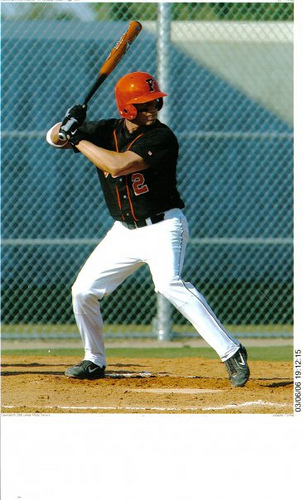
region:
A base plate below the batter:
[134, 385, 224, 396]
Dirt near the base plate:
[23, 382, 91, 401]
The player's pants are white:
[103, 243, 122, 278]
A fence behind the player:
[225, 188, 280, 271]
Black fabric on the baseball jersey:
[160, 166, 171, 202]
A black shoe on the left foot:
[228, 350, 247, 385]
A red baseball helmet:
[124, 81, 135, 96]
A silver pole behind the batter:
[157, 9, 170, 81]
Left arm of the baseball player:
[80, 140, 116, 174]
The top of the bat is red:
[107, 27, 140, 57]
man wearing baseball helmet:
[101, 74, 169, 141]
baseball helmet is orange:
[119, 80, 184, 110]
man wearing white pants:
[101, 238, 199, 291]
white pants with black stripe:
[188, 281, 211, 342]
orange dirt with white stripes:
[137, 368, 164, 387]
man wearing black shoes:
[220, 355, 255, 387]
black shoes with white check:
[228, 351, 259, 376]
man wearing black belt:
[120, 207, 177, 242]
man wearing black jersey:
[138, 133, 166, 175]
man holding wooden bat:
[51, 44, 129, 89]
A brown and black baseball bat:
[64, 12, 147, 115]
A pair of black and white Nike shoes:
[60, 338, 259, 394]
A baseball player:
[47, 68, 253, 393]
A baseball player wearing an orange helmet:
[47, 68, 185, 173]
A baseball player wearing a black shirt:
[50, 95, 201, 211]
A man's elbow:
[87, 149, 147, 185]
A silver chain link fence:
[190, 36, 288, 272]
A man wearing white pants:
[66, 203, 240, 349]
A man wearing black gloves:
[57, 98, 100, 154]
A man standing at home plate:
[37, 235, 264, 409]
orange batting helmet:
[111, 66, 176, 135]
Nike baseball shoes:
[218, 328, 257, 397]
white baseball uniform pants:
[65, 210, 249, 385]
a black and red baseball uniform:
[75, 122, 182, 227]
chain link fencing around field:
[215, 132, 292, 266]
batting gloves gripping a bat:
[46, 98, 93, 156]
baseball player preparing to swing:
[25, 19, 250, 385]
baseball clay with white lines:
[127, 364, 229, 413]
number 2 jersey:
[127, 166, 162, 201]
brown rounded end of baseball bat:
[75, 14, 150, 64]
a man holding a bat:
[52, 18, 178, 157]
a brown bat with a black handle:
[53, 12, 151, 145]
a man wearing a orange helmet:
[104, 71, 180, 135]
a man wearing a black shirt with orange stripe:
[81, 62, 192, 234]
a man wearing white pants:
[84, 151, 206, 485]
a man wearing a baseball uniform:
[75, 59, 236, 397]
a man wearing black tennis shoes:
[191, 312, 271, 401]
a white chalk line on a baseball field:
[98, 397, 262, 411]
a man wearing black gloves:
[49, 65, 180, 168]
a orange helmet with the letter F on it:
[114, 67, 165, 128]